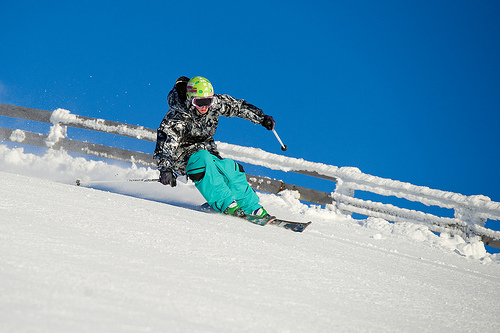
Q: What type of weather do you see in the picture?
A: It is clear.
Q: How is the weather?
A: It is clear.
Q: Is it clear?
A: Yes, it is clear.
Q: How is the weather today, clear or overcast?
A: It is clear.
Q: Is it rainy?
A: No, it is clear.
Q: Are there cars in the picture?
A: No, there are no cars.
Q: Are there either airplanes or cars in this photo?
A: No, there are no cars or airplanes.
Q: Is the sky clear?
A: Yes, the sky is clear.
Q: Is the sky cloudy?
A: No, the sky is clear.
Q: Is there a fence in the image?
A: Yes, there is a fence.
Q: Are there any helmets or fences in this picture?
A: Yes, there is a fence.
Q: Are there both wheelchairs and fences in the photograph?
A: No, there is a fence but no wheelchairs.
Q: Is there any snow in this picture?
A: Yes, there is snow.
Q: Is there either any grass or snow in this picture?
A: Yes, there is snow.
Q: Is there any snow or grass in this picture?
A: Yes, there is snow.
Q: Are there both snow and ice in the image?
A: No, there is snow but no ice.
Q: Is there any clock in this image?
A: No, there are no clocks.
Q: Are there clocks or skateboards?
A: No, there are no clocks or skateboards.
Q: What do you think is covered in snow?
A: The ground is covered in snow.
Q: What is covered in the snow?
A: The ground is covered in snow.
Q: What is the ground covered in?
A: The ground is covered in snow.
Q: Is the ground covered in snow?
A: Yes, the ground is covered in snow.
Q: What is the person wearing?
A: The person is wearing goggles.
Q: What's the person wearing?
A: The person is wearing goggles.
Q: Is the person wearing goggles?
A: Yes, the person is wearing goggles.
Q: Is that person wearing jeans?
A: No, the person is wearing goggles.